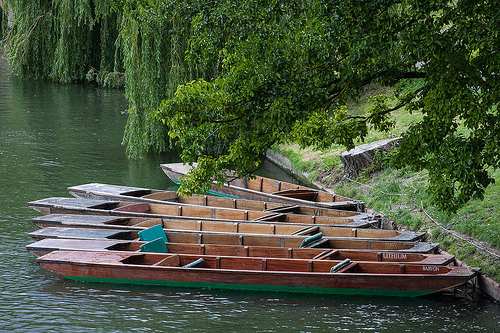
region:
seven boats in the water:
[6, 168, 295, 325]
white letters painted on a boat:
[378, 250, 427, 265]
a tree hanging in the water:
[80, 5, 217, 169]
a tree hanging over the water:
[41, 15, 447, 310]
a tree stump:
[330, 124, 419, 181]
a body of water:
[0, 87, 185, 235]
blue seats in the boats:
[119, 219, 179, 274]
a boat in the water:
[16, 247, 486, 315]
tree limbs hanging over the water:
[71, 36, 473, 310]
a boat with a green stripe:
[35, 260, 476, 301]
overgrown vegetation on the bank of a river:
[0, 0, 498, 329]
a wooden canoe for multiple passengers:
[37, 250, 479, 297]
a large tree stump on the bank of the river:
[340, 135, 410, 180]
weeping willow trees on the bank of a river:
[0, 0, 202, 158]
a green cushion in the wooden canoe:
[138, 223, 168, 244]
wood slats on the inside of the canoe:
[262, 257, 267, 269]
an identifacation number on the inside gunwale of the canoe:
[382, 252, 407, 260]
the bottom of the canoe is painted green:
[64, 272, 472, 297]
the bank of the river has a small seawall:
[247, 142, 340, 193]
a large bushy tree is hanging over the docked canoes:
[159, 0, 499, 213]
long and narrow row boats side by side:
[26, 135, 467, 301]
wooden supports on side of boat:
[190, 200, 296, 265]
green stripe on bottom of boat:
[57, 250, 442, 305]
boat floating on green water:
[27, 250, 472, 330]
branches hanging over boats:
[155, 55, 320, 207]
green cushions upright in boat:
[107, 210, 172, 260]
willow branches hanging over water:
[115, 26, 171, 171]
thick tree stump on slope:
[335, 130, 430, 180]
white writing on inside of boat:
[380, 240, 445, 276]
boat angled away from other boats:
[62, 145, 359, 233]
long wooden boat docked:
[33, 248, 483, 298]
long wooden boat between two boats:
[21, 237, 453, 262]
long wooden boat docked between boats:
[27, 222, 438, 252]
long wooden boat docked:
[26, 206, 421, 241]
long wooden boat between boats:
[26, 192, 373, 224]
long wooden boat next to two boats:
[66, 177, 377, 217]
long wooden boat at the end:
[160, 155, 365, 207]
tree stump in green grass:
[337, 131, 402, 176]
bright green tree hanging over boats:
[150, 1, 492, 213]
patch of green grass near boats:
[270, 75, 497, 288]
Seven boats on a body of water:
[11, 136, 486, 310]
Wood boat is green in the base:
[36, 245, 486, 315]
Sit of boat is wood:
[131, 236, 170, 258]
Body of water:
[0, 64, 159, 178]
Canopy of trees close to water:
[6, 0, 496, 123]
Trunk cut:
[328, 127, 418, 184]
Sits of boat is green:
[324, 251, 355, 276]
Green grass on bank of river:
[303, 74, 496, 254]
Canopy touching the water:
[96, 69, 178, 171]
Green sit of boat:
[131, 211, 171, 241]